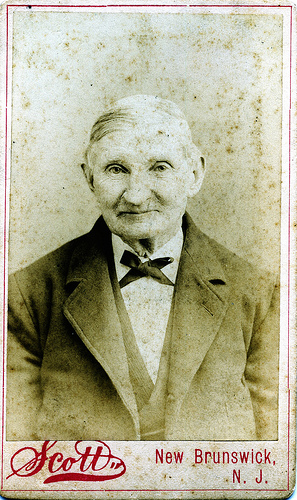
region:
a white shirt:
[135, 297, 165, 325]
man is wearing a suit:
[53, 321, 117, 409]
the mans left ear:
[186, 155, 208, 194]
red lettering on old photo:
[154, 446, 274, 464]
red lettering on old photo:
[9, 438, 126, 476]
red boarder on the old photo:
[0, 1, 290, 492]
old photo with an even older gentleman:
[5, 91, 277, 440]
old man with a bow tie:
[113, 240, 176, 292]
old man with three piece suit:
[8, 211, 278, 446]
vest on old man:
[100, 221, 186, 438]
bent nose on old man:
[124, 168, 147, 205]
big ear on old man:
[186, 152, 206, 199]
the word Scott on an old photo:
[8, 442, 127, 486]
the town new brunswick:
[154, 448, 271, 464]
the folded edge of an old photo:
[284, 488, 295, 498]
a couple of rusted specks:
[163, 472, 173, 480]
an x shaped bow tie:
[118, 251, 173, 288]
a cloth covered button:
[166, 393, 174, 401]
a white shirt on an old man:
[110, 233, 183, 383]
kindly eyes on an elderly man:
[107, 161, 172, 176]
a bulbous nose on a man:
[125, 179, 151, 205]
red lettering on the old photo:
[155, 446, 272, 467]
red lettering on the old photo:
[229, 465, 268, 484]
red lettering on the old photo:
[4, 440, 125, 482]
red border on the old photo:
[1, 2, 287, 492]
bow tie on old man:
[114, 247, 174, 288]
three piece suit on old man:
[3, 210, 277, 442]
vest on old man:
[101, 216, 193, 448]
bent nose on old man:
[124, 168, 152, 205]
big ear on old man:
[80, 158, 98, 194]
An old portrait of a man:
[3, 0, 295, 499]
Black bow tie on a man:
[115, 248, 174, 289]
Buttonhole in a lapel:
[198, 301, 215, 317]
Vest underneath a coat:
[111, 269, 170, 439]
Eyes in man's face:
[105, 159, 169, 175]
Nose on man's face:
[122, 175, 152, 206]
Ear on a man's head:
[187, 154, 206, 196]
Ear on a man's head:
[79, 161, 96, 196]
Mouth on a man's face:
[114, 207, 161, 216]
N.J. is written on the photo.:
[226, 465, 270, 488]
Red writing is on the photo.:
[10, 438, 282, 490]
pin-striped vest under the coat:
[102, 228, 192, 440]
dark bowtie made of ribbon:
[113, 249, 175, 288]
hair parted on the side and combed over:
[87, 94, 201, 177]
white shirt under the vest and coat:
[109, 224, 184, 398]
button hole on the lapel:
[196, 295, 216, 323]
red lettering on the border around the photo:
[4, 436, 287, 487]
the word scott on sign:
[2, 441, 130, 492]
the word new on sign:
[150, 442, 187, 472]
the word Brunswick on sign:
[190, 443, 274, 466]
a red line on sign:
[0, 486, 281, 491]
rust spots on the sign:
[150, 472, 203, 486]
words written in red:
[1, 437, 283, 494]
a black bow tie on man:
[111, 246, 180, 292]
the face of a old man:
[74, 89, 207, 237]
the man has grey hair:
[77, 93, 207, 241]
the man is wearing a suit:
[4, 90, 284, 443]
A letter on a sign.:
[164, 445, 171, 466]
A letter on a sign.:
[204, 451, 212, 462]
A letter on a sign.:
[213, 449, 217, 462]